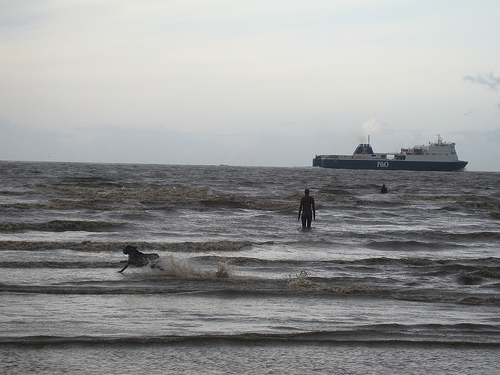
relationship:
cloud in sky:
[459, 66, 499, 91] [1, 1, 499, 170]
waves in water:
[157, 253, 242, 283] [3, 158, 498, 374]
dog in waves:
[118, 244, 165, 274] [157, 253, 242, 283]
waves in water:
[284, 269, 373, 298] [3, 158, 498, 374]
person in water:
[297, 187, 318, 231] [3, 158, 498, 374]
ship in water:
[312, 133, 469, 170] [3, 158, 498, 374]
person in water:
[379, 181, 390, 197] [3, 158, 498, 374]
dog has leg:
[118, 244, 165, 274] [116, 261, 130, 274]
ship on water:
[312, 133, 469, 170] [3, 158, 498, 374]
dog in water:
[118, 244, 165, 274] [3, 158, 498, 374]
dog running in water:
[118, 244, 165, 274] [3, 158, 498, 374]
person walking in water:
[297, 187, 318, 231] [3, 158, 498, 374]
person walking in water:
[379, 181, 390, 197] [3, 158, 498, 374]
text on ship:
[375, 158, 391, 169] [312, 133, 469, 170]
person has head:
[297, 187, 318, 231] [304, 188, 311, 197]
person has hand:
[297, 187, 318, 231] [297, 213, 302, 221]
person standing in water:
[297, 187, 318, 231] [3, 158, 498, 374]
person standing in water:
[379, 181, 390, 197] [3, 158, 498, 374]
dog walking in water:
[118, 244, 165, 274] [3, 158, 498, 374]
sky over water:
[1, 1, 499, 170] [3, 158, 498, 374]